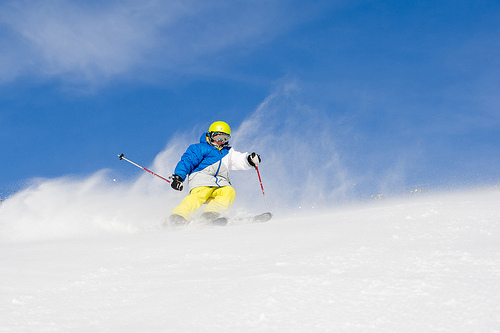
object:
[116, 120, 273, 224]
skier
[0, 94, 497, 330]
snow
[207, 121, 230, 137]
helmet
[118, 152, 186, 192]
ski pole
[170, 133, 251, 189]
jacket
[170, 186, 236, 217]
pants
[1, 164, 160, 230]
kicked up snow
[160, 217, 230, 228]
skis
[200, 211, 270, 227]
snow skis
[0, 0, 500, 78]
sky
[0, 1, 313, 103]
light clouds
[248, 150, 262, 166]
gloves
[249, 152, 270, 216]
ski pole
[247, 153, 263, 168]
hand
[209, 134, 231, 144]
goggles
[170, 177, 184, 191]
glove